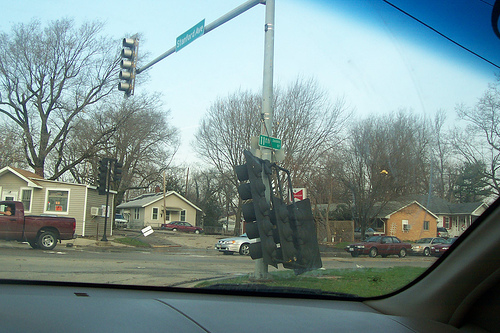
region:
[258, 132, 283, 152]
A green and white street sign that says 11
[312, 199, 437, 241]
A brown brick house with black pitched roof.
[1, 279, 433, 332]
A dark grey dash.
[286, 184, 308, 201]
A white sign with red design on it.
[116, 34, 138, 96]
A silver 5 light traffic light up on a pole over the road.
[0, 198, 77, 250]
A red truck with a man driving.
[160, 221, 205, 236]
A red car parked up by a tan house with a large roof.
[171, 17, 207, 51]
A green and white street sign up by a silver traffic light.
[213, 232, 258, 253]
A silver car obstructed by black lights on the ground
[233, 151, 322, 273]
Two large black street lights on the ground.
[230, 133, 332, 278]
Broken signal lights on the pole.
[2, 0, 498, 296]
Front window on the car.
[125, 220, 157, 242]
White sign leaning to the ground.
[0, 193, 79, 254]
Truck on the road.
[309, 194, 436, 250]
Brick house in the background.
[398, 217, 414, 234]
Air conditioner in the window.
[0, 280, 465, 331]
Dashboard on the car.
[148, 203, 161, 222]
Window on the house.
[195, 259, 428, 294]
Green grass covering the ground.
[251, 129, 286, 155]
Green sign on the post.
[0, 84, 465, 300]
windshield lets you view a wide scene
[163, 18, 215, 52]
road name is attached to pole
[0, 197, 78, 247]
driver has window down with arm resting on frame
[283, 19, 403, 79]
clear skies today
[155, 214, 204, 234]
car is parked in front of the house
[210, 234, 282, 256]
silver car behind the sign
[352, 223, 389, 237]
car is parked between tree and house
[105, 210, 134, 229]
white vehicle parked between two buildings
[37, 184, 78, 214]
red sign in the window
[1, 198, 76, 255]
a red pickup truck on a road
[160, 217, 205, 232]
a red car parked next to a house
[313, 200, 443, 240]
a red brick house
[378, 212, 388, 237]
a drain pipe on the side of a house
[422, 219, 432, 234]
a window on a brick house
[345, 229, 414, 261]
a red car near a brick house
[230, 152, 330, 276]
a fallen down set of stop lights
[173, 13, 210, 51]
a green and white street sign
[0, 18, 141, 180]
a bare leafless tree behind a small building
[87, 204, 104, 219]
an air conditioner unit on the side of a small building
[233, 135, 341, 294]
a traffic light hanging by a cord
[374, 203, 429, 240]
a brick house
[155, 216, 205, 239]
a car parked in front of a house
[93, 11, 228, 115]
a traffic light on a pole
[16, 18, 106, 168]
a tree with no leaves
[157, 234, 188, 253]
a curb painted yellow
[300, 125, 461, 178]
several trees with no leaves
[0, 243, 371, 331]
the dashboard of a vehicle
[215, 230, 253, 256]
the front of a car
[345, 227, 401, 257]
a red car in the street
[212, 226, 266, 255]
silver car on the road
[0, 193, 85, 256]
red truck on the road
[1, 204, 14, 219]
driver of a red truck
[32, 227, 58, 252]
back tire of a red truck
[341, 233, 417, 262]
fully visible red car on the road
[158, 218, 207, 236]
red car in front of a house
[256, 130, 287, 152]
green road sign on a vertical post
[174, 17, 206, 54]
green road sign on a vertical post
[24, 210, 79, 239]
bed of a truck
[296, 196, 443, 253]
building made of brick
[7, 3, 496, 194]
The cloudy sky